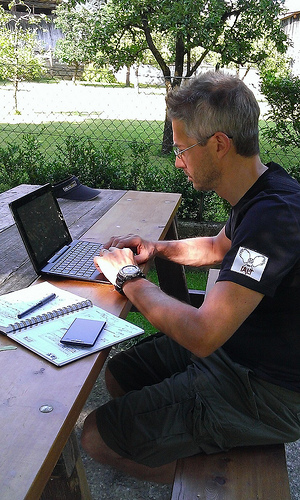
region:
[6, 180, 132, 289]
Laptop on the table top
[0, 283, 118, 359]
Pen and cellphone on the top of the notebook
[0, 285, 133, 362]
Spiral notebook on the top of the table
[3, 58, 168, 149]
Chain link fence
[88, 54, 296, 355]
man working on his laptop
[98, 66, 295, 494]
man wearing black shirt and shorts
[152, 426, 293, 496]
dark wooden chair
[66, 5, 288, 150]
Trees beside the chain link fence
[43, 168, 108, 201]
hat on the top of the table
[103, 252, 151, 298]
big black watch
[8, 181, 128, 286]
a black laptop is on the table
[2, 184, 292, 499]
the picnic table is wooden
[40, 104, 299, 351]
a man is typing on the laptop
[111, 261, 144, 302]
a black watch is on the person's wrist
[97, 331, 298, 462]
the man is wearing shorts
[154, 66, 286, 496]
the man is sitting on a bench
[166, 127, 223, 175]
the man is wearing eyeglasses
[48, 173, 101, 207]
a black visor is on the picnic table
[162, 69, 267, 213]
the man's hair is graying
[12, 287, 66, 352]
a pen is on a spiral notebook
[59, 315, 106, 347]
Smartphone with its screen disabled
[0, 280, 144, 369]
Spiral notebook with a black cover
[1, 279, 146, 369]
Spiral notebook with notes written into it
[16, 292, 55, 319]
Pen with its cap on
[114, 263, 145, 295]
Wristwatch made of a dark tinted metal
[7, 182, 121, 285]
Open laptop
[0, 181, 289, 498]
Wooden picnic bench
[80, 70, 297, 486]
Men wearing glasses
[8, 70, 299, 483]
Man working on his laptop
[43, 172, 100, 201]
Dark colored visor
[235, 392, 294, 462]
he is sitting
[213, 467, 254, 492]
the bench is brown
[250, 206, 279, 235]
the shirt is black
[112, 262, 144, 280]
he wearing a watch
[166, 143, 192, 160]
he is wearing glasses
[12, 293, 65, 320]
the pen is on the notepad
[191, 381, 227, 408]
the shirts are gray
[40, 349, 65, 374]
the notepad is on the table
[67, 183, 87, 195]
the visor is blue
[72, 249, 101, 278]
the laptop is black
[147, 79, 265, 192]
face of the person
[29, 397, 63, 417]
a small bolt in wood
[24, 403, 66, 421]
a bolt in table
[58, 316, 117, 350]
a mobile in file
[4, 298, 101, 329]
a thread to hold book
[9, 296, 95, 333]
a thread for binding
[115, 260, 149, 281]
watch of the person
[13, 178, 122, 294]
a nice wide laptop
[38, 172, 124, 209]
a cap placed in table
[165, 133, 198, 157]
a spects wearing by person